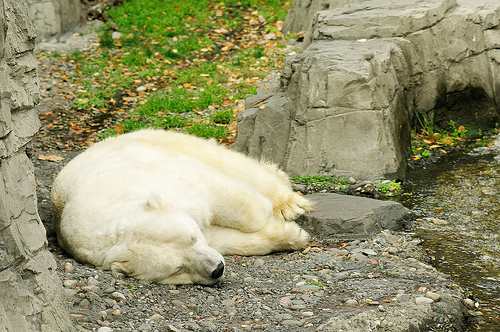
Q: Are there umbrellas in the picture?
A: No, there are no umbrellas.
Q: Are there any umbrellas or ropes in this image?
A: No, there are no umbrellas or ropes.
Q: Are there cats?
A: No, there are no cats.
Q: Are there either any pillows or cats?
A: No, there are no cats or pillows.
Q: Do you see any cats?
A: No, there are no cats.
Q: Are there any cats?
A: No, there are no cats.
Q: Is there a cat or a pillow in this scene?
A: No, there are no cats or pillows.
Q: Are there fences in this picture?
A: No, there are no fences.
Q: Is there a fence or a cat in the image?
A: No, there are no fences or cats.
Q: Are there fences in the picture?
A: No, there are no fences.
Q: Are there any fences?
A: No, there are no fences.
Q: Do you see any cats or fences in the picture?
A: No, there are no fences or cats.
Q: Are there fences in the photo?
A: No, there are no fences.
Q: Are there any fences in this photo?
A: No, there are no fences.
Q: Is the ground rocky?
A: Yes, the ground is rocky.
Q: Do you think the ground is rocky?
A: Yes, the ground is rocky.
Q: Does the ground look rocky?
A: Yes, the ground is rocky.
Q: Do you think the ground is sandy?
A: No, the ground is rocky.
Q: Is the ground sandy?
A: No, the ground is rocky.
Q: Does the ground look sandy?
A: No, the ground is rocky.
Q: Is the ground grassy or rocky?
A: The ground is rocky.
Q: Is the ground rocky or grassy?
A: The ground is rocky.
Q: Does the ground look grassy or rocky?
A: The ground is rocky.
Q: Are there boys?
A: No, there are no boys.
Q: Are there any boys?
A: No, there are no boys.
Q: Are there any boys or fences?
A: No, there are no boys or fences.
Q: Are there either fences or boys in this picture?
A: No, there are no boys or fences.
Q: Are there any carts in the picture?
A: No, there are no carts.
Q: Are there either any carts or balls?
A: No, there are no carts or balls.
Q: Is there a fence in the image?
A: No, there are no fences.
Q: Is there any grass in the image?
A: Yes, there is grass.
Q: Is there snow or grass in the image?
A: Yes, there is grass.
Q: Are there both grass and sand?
A: No, there is grass but no sand.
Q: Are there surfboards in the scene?
A: No, there are no surfboards.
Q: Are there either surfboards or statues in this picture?
A: No, there are no surfboards or statues.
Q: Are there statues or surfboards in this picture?
A: No, there are no surfboards or statues.